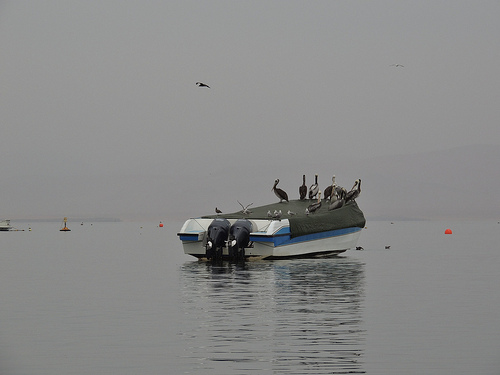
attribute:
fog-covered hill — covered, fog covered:
[124, 160, 484, 225]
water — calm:
[285, 298, 468, 345]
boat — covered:
[164, 181, 376, 278]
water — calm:
[2, 222, 498, 373]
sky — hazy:
[3, 2, 498, 214]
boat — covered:
[177, 189, 366, 265]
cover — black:
[204, 195, 366, 236]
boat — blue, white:
[161, 197, 389, 277]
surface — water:
[11, 281, 497, 364]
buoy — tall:
[51, 214, 70, 236]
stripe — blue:
[265, 220, 356, 240]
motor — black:
[207, 219, 250, 263]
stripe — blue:
[264, 225, 339, 244]